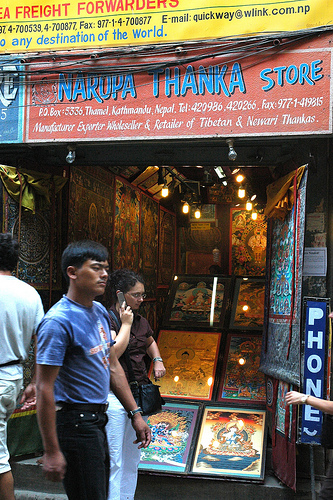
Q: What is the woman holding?
A: The woman is holding a phone.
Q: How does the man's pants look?
A: The pants are black in color.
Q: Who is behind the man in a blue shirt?
A: A man with a white shirt.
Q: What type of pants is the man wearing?
A: The man is wearing black pants.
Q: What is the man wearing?
A: The man is wearing a blue shirt.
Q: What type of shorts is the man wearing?
A: The man is wearing khaki shorts.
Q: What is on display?
A: 6 art works for display in a store.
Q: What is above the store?
A: A large orange sign with big blue lettering and small white letters.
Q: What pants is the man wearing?
A: Black pants being worn by a person.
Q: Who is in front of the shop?
A: A woman on the phone.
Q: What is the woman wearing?
A: Woman wearing white pants.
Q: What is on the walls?
A: Rugs.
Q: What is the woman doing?
A: On the phone.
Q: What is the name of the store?
A: Naropa Thanka.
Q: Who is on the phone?
A: The woman.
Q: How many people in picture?
A: Three.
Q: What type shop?
A: Art, pictures.